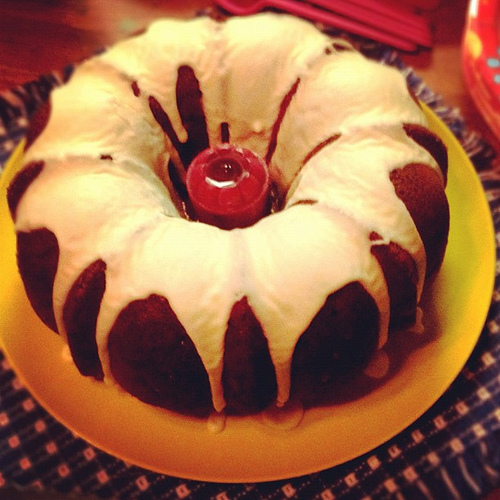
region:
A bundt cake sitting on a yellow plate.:
[11, 89, 498, 486]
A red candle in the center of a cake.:
[187, 139, 272, 231]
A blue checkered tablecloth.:
[407, 439, 497, 498]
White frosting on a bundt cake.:
[9, 13, 455, 424]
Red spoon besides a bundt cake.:
[215, 1, 435, 56]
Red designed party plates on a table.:
[459, 1, 498, 161]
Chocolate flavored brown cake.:
[131, 317, 182, 397]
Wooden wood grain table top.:
[4, 4, 64, 57]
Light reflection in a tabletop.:
[67, 0, 194, 44]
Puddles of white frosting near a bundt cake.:
[204, 409, 306, 436]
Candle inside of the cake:
[182, 145, 270, 232]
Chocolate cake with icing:
[5, 11, 450, 428]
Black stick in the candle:
[217, 161, 237, 181]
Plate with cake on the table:
[1, 18, 492, 482]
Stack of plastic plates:
[462, 1, 497, 143]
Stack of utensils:
[214, 2, 432, 60]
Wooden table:
[1, 0, 213, 92]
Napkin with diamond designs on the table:
[0, 25, 497, 495]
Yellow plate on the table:
[2, 85, 494, 483]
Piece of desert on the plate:
[11, 11, 451, 422]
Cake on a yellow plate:
[12, 33, 482, 396]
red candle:
[166, 130, 302, 232]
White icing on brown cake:
[296, 88, 431, 237]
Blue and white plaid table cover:
[4, 408, 46, 480]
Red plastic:
[214, 3, 439, 62]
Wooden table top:
[3, 10, 59, 60]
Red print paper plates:
[451, 1, 498, 135]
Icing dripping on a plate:
[161, 366, 337, 456]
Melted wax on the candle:
[179, 140, 282, 228]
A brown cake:
[376, 148, 471, 328]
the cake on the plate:
[61, 14, 447, 389]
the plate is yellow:
[15, 100, 483, 496]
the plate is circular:
[8, 103, 499, 490]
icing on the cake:
[51, 119, 172, 261]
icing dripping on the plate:
[259, 407, 314, 436]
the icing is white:
[41, 128, 178, 273]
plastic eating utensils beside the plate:
[216, 2, 442, 52]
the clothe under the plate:
[6, 390, 498, 498]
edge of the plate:
[213, 465, 320, 487]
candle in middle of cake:
[178, 126, 275, 210]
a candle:
[192, 149, 277, 207]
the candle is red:
[183, 142, 276, 212]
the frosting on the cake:
[181, 254, 263, 294]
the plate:
[118, 414, 180, 455]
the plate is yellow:
[328, 421, 374, 448]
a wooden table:
[16, 28, 66, 60]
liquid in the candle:
[212, 163, 227, 181]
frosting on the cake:
[198, 251, 272, 288]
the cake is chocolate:
[123, 334, 172, 381]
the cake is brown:
[138, 342, 183, 382]